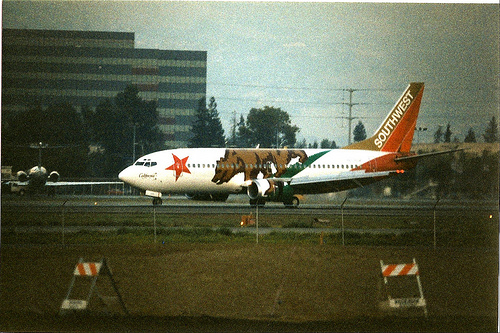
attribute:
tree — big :
[64, 83, 174, 140]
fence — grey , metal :
[1, 188, 498, 263]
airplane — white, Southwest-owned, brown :
[118, 81, 471, 209]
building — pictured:
[2, 25, 210, 186]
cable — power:
[342, 86, 366, 115]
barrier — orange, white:
[362, 224, 436, 308]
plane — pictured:
[115, 79, 425, 209]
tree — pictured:
[182, 90, 239, 155]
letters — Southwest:
[368, 84, 417, 152]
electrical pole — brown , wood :
[333, 72, 368, 153]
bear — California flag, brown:
[212, 143, 346, 184]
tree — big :
[193, 85, 226, 155]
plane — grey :
[8, 146, 70, 208]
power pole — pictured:
[345, 85, 357, 147]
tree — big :
[83, 84, 172, 174]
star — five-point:
[164, 150, 199, 186]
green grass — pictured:
[14, 233, 496, 331]